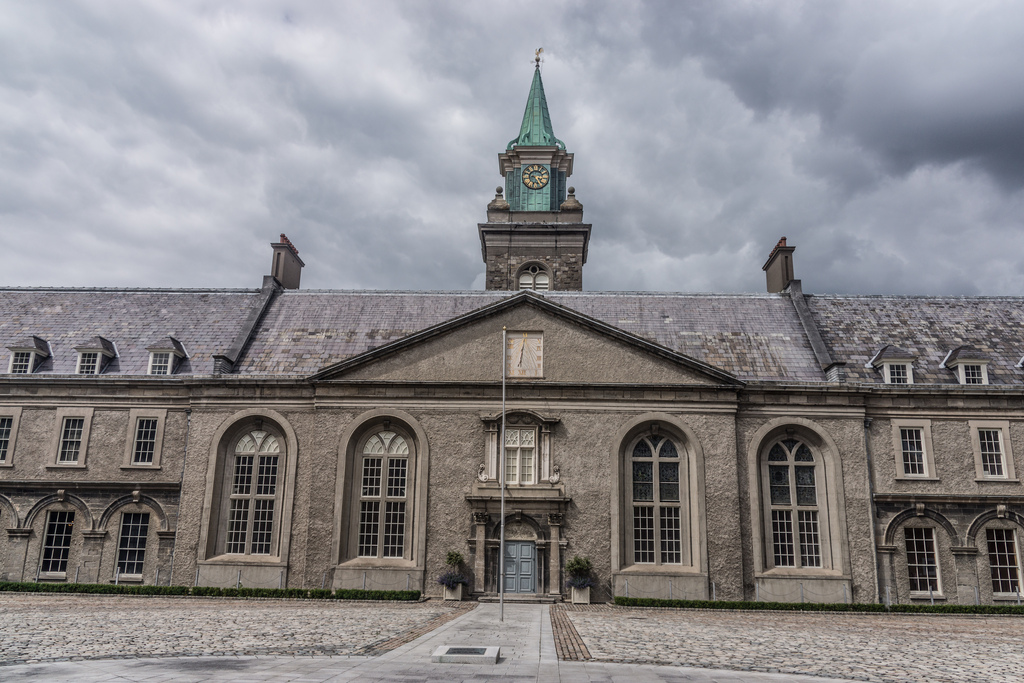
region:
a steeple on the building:
[471, 40, 607, 294]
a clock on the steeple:
[522, 161, 552, 193]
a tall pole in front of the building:
[489, 319, 516, 617]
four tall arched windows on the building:
[187, 407, 843, 598]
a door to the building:
[492, 531, 546, 599]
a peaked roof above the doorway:
[315, 290, 743, 390]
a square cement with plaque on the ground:
[429, 636, 512, 665]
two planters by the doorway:
[433, 544, 598, 606]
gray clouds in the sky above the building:
[18, 18, 1015, 298]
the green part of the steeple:
[496, 53, 574, 213]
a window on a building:
[43, 406, 83, 455]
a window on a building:
[132, 380, 167, 467]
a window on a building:
[225, 424, 277, 542]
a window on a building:
[340, 428, 417, 572]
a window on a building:
[765, 436, 841, 588]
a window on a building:
[895, 405, 930, 482]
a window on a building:
[891, 507, 943, 593]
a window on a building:
[976, 507, 1022, 597]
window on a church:
[220, 405, 291, 586]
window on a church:
[339, 418, 441, 581]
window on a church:
[612, 417, 683, 588]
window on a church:
[744, 421, 846, 587]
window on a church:
[894, 412, 924, 482]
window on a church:
[881, 497, 949, 608]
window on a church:
[26, 506, 74, 584]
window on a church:
[103, 500, 164, 593]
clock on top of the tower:
[515, 155, 551, 190]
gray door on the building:
[490, 521, 541, 605]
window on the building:
[141, 342, 176, 372]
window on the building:
[69, 345, 111, 384]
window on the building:
[9, 339, 41, 372]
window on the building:
[891, 418, 934, 486]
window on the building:
[972, 420, 1015, 479]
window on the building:
[885, 354, 909, 383]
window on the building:
[599, 413, 714, 581]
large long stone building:
[1, 47, 1022, 632]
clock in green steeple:
[513, 148, 562, 203]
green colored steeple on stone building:
[474, 51, 602, 211]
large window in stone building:
[338, 417, 422, 551]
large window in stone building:
[227, 421, 294, 561]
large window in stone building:
[609, 404, 702, 586]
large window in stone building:
[742, 392, 838, 580]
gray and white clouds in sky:
[837, 35, 958, 220]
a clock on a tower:
[462, 26, 609, 235]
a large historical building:
[5, 28, 1009, 638]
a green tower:
[484, 40, 599, 206]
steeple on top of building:
[474, 42, 614, 296]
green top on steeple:
[498, 35, 568, 166]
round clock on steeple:
[517, 155, 575, 203]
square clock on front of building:
[488, 315, 566, 386]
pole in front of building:
[490, 318, 522, 672]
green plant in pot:
[558, 543, 603, 592]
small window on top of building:
[136, 327, 193, 395]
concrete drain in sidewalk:
[424, 631, 511, 670]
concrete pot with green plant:
[424, 545, 485, 610]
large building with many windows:
[1, 252, 1019, 644]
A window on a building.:
[616, 430, 684, 566]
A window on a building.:
[765, 424, 827, 567]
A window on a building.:
[898, 422, 924, 465]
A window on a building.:
[972, 427, 1002, 476]